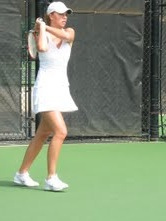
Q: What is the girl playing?
A: Tennis.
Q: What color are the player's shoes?
A: White.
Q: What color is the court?
A: Green.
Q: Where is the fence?
A: Behind the player.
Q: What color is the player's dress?
A: White.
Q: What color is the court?
A: Green.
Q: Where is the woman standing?
A: Tennis court.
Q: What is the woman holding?
A: Tennis racket.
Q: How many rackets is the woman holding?
A: One.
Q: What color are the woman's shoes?
A: White.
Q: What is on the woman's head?
A: Hat.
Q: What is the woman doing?
A: Playing Tennis.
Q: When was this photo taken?
A: During a game of tennis.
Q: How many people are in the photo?
A: 1.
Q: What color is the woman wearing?
A: White.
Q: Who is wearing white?
A: The woman.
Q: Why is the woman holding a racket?
A: To hit the ball.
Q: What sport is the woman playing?
A: Tennis.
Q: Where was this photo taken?
A: On a tennis court.